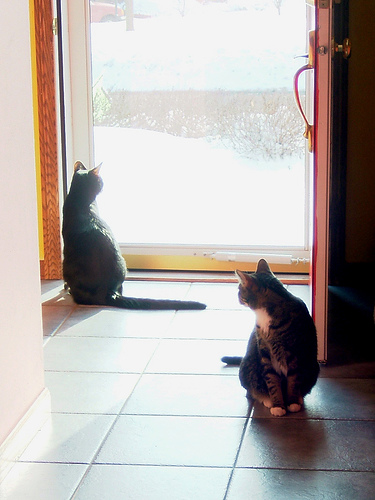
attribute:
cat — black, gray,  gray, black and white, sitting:
[224, 254, 320, 416]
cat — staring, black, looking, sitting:
[59, 159, 209, 316]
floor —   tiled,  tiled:
[2, 279, 375, 500]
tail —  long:
[113, 295, 206, 313]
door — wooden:
[292, 5, 350, 364]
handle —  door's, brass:
[292, 30, 315, 154]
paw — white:
[269, 402, 287, 418]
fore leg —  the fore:
[263, 366, 286, 416]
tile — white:
[93, 413, 247, 468]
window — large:
[55, 3, 313, 262]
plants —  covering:
[91, 90, 316, 162]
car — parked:
[66, 0, 129, 25]